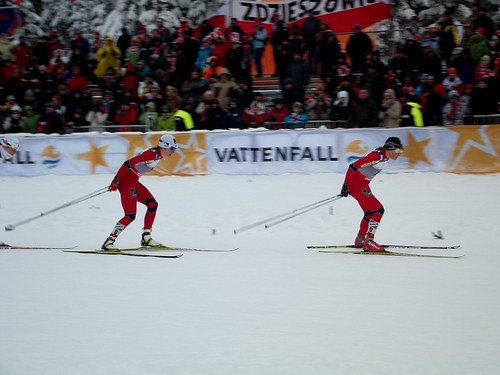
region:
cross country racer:
[100, 136, 187, 260]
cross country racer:
[335, 129, 412, 279]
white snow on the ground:
[154, 281, 192, 305]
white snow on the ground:
[265, 345, 296, 369]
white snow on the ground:
[102, 312, 173, 366]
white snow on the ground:
[241, 329, 286, 371]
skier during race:
[110, 119, 182, 254]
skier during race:
[328, 113, 420, 278]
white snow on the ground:
[342, 262, 377, 322]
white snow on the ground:
[225, 289, 280, 340]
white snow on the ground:
[85, 291, 149, 358]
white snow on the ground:
[235, 315, 302, 373]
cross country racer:
[100, 131, 162, 263]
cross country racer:
[327, 115, 394, 275]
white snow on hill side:
[284, 315, 335, 373]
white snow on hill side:
[384, 278, 434, 360]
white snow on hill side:
[225, 301, 270, 349]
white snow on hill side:
[108, 283, 159, 334]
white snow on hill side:
[31, 296, 95, 344]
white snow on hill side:
[250, 299, 288, 326]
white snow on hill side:
[328, 308, 403, 359]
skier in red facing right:
[335, 133, 404, 253]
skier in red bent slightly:
[332, 134, 407, 255]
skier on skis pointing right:
[302, 130, 471, 267]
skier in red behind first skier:
[97, 133, 181, 255]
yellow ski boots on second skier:
[96, 228, 168, 256]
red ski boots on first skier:
[350, 228, 391, 253]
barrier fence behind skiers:
[2, 118, 497, 179]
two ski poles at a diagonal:
[230, 193, 350, 235]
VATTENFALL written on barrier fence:
[212, 144, 339, 167]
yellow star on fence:
[70, 135, 114, 177]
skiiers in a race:
[13, 124, 468, 301]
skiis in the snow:
[313, 241, 465, 267]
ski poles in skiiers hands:
[238, 189, 337, 241]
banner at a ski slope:
[181, 129, 347, 179]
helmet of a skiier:
[154, 129, 179, 149]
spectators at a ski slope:
[36, 30, 445, 120]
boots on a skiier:
[86, 235, 173, 251]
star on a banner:
[174, 132, 212, 174]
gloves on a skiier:
[334, 177, 354, 212]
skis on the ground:
[294, 214, 466, 280]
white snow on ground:
[257, 290, 362, 342]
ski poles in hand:
[201, 183, 344, 275]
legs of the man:
[341, 195, 397, 250]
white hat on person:
[141, 130, 196, 170]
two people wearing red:
[44, 131, 431, 280]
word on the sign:
[198, 129, 353, 199]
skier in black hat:
[337, 135, 414, 261]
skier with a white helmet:
[102, 129, 178, 257]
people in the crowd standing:
[66, 37, 171, 99]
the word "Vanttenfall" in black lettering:
[214, 144, 338, 166]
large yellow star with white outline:
[444, 125, 497, 157]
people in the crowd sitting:
[246, 102, 307, 122]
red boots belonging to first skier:
[353, 233, 386, 254]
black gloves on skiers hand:
[341, 183, 349, 198]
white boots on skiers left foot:
[141, 230, 161, 249]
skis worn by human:
[68, 240, 233, 260]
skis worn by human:
[298, 235, 462, 261]